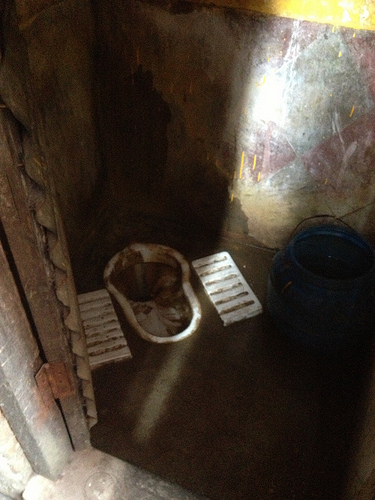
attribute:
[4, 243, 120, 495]
doorway — concrete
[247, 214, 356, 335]
vase — blue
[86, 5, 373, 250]
wall — concrete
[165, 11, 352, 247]
wall — yellow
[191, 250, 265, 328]
plastic — white